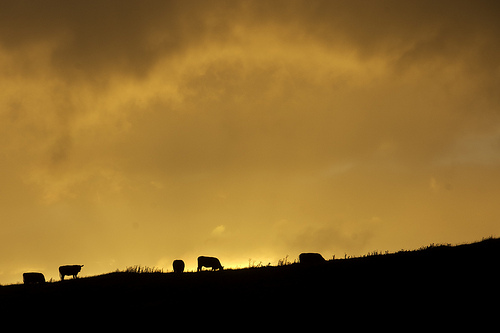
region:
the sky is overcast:
[1, 28, 465, 243]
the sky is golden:
[2, 30, 477, 224]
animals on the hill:
[147, 237, 346, 269]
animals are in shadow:
[13, 226, 355, 289]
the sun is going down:
[162, 240, 290, 290]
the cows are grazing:
[123, 232, 340, 276]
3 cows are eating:
[152, 239, 343, 299]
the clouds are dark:
[30, 10, 439, 140]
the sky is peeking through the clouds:
[388, 112, 493, 196]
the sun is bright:
[228, 242, 278, 270]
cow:
[55, 253, 96, 287]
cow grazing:
[197, 250, 225, 276]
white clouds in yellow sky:
[23, 44, 67, 101]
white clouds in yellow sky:
[231, 169, 275, 200]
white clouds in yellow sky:
[333, 117, 391, 185]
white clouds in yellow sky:
[138, 112, 220, 185]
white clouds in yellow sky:
[252, 66, 358, 159]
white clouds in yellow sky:
[125, 190, 178, 215]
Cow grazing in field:
[196, 253, 221, 268]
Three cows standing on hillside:
[56, 250, 322, 275]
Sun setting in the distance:
[157, 255, 283, 270]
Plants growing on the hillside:
[245, 255, 290, 266]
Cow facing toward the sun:
[170, 256, 180, 267]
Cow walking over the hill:
[296, 251, 321, 261]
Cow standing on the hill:
[57, 263, 87, 278]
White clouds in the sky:
[24, 170, 104, 209]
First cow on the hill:
[297, 251, 325, 264]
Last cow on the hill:
[21, 270, 43, 282]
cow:
[53, 260, 81, 279]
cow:
[299, 238, 329, 264]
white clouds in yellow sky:
[21, 17, 73, 67]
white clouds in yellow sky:
[121, 20, 168, 70]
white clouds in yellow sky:
[75, 112, 170, 172]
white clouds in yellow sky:
[278, 58, 328, 111]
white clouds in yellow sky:
[378, 41, 419, 102]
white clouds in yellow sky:
[294, 136, 338, 172]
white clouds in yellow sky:
[364, 189, 410, 211]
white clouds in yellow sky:
[32, 174, 95, 204]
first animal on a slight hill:
[296, 247, 326, 263]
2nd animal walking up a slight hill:
[197, 252, 224, 274]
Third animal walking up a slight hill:
[171, 258, 186, 272]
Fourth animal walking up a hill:
[53, 262, 85, 283]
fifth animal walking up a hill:
[18, 269, 50, 286]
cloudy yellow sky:
[3, 3, 498, 288]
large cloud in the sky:
[6, 2, 498, 183]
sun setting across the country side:
[191, 262, 288, 270]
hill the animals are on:
[1, 232, 493, 331]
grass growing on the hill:
[343, 254, 386, 261]